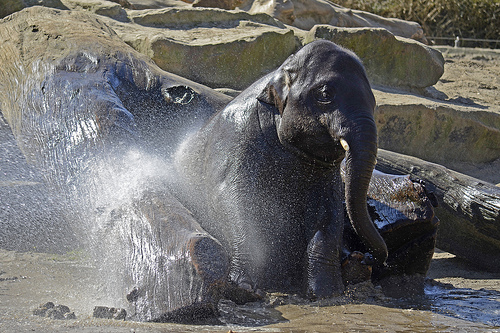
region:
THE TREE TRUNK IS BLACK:
[447, 196, 461, 236]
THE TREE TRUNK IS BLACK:
[460, 195, 470, 231]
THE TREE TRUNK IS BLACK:
[477, 171, 485, 233]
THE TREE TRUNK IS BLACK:
[444, 205, 458, 245]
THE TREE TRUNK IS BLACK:
[457, 186, 465, 219]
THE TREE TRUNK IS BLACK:
[434, 185, 452, 217]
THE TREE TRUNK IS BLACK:
[419, 180, 447, 216]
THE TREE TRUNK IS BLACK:
[444, 189, 451, 244]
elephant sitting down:
[145, 38, 416, 308]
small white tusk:
[336, 136, 352, 151]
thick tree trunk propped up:
[8, 16, 238, 318]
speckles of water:
[107, 102, 194, 195]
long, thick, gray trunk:
[346, 111, 399, 263]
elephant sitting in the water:
[143, 21, 415, 309]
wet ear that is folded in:
[251, 52, 307, 127]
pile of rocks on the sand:
[33, 293, 80, 321]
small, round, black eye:
[310, 82, 337, 109]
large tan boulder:
[314, 18, 459, 92]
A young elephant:
[227, 36, 387, 201]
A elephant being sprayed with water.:
[115, 81, 325, 262]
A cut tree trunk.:
[55, 52, 136, 235]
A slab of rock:
[130, 6, 281, 52]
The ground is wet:
[310, 300, 420, 330]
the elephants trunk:
[337, 147, 378, 257]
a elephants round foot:
[227, 261, 263, 301]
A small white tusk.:
[335, 132, 350, 150]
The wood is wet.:
[101, 168, 172, 251]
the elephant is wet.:
[236, 65, 376, 230]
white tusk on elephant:
[337, 127, 356, 159]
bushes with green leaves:
[423, 5, 497, 42]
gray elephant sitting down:
[153, 66, 419, 302]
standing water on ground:
[297, 297, 467, 332]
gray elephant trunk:
[342, 107, 392, 274]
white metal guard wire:
[434, 30, 499, 47]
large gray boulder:
[311, 15, 446, 67]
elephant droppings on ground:
[28, 295, 81, 325]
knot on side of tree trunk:
[153, 67, 206, 117]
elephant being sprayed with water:
[130, 57, 417, 309]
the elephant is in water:
[54, 29, 421, 304]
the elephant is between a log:
[54, 31, 451, 307]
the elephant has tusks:
[84, 28, 474, 314]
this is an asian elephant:
[79, 22, 463, 285]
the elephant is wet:
[80, 22, 430, 302]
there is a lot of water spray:
[63, 34, 420, 328]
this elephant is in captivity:
[43, 30, 458, 322]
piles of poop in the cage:
[21, 279, 187, 331]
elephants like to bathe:
[111, 16, 461, 322]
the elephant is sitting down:
[41, 19, 493, 265]